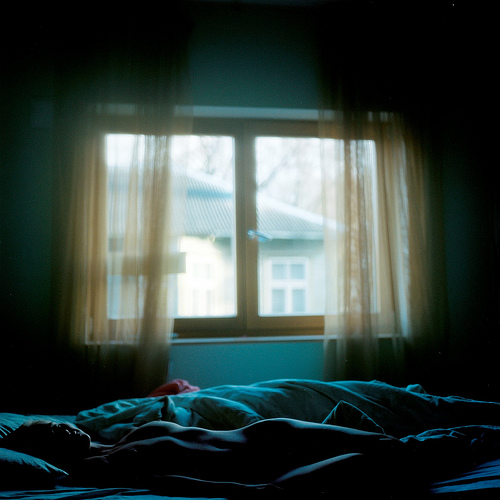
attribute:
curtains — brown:
[44, 1, 195, 400]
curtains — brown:
[316, 2, 456, 396]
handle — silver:
[247, 230, 272, 243]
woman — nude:
[7, 407, 441, 497]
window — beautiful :
[80, 110, 410, 344]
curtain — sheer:
[50, 7, 190, 401]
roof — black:
[110, 166, 352, 246]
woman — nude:
[3, 417, 405, 498]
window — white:
[265, 255, 312, 315]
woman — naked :
[116, 407, 252, 479]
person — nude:
[5, 408, 498, 500]